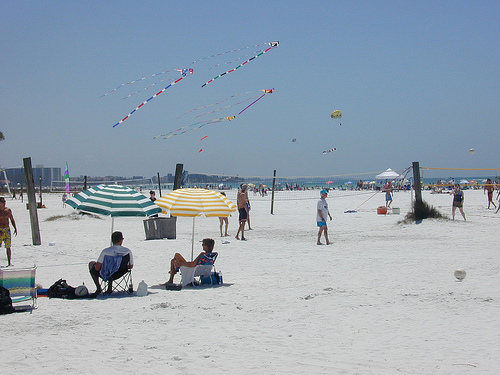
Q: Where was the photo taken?
A: It was taken at the beach.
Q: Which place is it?
A: It is a beach.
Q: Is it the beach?
A: Yes, it is the beach.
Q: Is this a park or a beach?
A: It is a beach.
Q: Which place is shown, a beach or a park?
A: It is a beach.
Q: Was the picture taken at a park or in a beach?
A: It was taken at a beach.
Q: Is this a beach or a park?
A: It is a beach.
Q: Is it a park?
A: No, it is a beach.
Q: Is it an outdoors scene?
A: Yes, it is outdoors.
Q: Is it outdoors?
A: Yes, it is outdoors.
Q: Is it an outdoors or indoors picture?
A: It is outdoors.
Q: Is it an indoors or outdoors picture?
A: It is outdoors.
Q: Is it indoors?
A: No, it is outdoors.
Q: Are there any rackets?
A: No, there are no rackets.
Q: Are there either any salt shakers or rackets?
A: No, there are no rackets or salt shakers.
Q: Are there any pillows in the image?
A: No, there are no pillows.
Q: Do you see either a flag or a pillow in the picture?
A: No, there are no pillows or flags.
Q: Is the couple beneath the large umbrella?
A: Yes, the couple is beneath the umbrella.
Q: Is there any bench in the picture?
A: No, there are no benches.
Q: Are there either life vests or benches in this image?
A: No, there are no benches or life vests.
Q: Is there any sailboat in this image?
A: No, there are no sailboats.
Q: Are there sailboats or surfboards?
A: No, there are no sailboats or surfboards.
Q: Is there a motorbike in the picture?
A: No, there are no motorcycles.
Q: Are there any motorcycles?
A: No, there are no motorcycles.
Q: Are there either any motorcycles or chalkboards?
A: No, there are no motorcycles or chalkboards.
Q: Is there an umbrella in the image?
A: Yes, there is an umbrella.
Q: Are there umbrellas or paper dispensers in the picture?
A: Yes, there is an umbrella.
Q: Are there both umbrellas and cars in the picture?
A: No, there is an umbrella but no cars.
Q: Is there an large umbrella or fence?
A: Yes, there is a large umbrella.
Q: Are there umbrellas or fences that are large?
A: Yes, the umbrella is large.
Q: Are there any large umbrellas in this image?
A: Yes, there is a large umbrella.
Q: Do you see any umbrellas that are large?
A: Yes, there is an umbrella that is large.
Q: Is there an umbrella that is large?
A: Yes, there is an umbrella that is large.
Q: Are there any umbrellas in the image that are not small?
A: Yes, there is a large umbrella.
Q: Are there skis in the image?
A: No, there are no skis.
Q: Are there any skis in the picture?
A: No, there are no skis.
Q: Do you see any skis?
A: No, there are no skis.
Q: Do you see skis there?
A: No, there are no skis.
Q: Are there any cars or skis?
A: No, there are no skis or cars.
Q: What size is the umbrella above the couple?
A: The umbrella is large.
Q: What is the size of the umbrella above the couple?
A: The umbrella is large.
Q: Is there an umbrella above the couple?
A: Yes, there is an umbrella above the couple.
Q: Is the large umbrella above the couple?
A: Yes, the umbrella is above the couple.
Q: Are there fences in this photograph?
A: No, there are no fences.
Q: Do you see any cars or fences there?
A: No, there are no fences or cars.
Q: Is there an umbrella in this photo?
A: Yes, there is an umbrella.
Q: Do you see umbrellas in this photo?
A: Yes, there is an umbrella.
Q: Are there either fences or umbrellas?
A: Yes, there is an umbrella.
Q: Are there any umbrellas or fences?
A: Yes, there is an umbrella.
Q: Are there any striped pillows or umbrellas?
A: Yes, there is a striped umbrella.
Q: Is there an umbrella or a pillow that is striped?
A: Yes, the umbrella is striped.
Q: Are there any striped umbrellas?
A: Yes, there is a striped umbrella.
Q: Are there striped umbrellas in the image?
A: Yes, there is a striped umbrella.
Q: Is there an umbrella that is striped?
A: Yes, there is an umbrella that is striped.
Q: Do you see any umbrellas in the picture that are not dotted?
A: Yes, there is a striped umbrella.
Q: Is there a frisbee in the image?
A: No, there are no frisbees.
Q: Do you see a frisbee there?
A: No, there are no frisbees.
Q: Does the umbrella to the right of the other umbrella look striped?
A: Yes, the umbrella is striped.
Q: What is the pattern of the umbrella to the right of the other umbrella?
A: The umbrella is striped.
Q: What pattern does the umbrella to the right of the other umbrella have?
A: The umbrella has striped pattern.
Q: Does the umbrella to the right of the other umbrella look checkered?
A: No, the umbrella is striped.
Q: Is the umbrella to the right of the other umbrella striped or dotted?
A: The umbrella is striped.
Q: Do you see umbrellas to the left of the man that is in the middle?
A: Yes, there is an umbrella to the left of the man.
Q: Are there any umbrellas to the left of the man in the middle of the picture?
A: Yes, there is an umbrella to the left of the man.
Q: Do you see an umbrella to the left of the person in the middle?
A: Yes, there is an umbrella to the left of the man.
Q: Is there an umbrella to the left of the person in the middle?
A: Yes, there is an umbrella to the left of the man.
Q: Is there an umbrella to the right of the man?
A: No, the umbrella is to the left of the man.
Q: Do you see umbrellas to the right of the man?
A: No, the umbrella is to the left of the man.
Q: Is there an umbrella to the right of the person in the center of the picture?
A: No, the umbrella is to the left of the man.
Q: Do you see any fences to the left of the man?
A: No, there is an umbrella to the left of the man.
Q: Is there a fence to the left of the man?
A: No, there is an umbrella to the left of the man.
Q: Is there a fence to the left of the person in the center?
A: No, there is an umbrella to the left of the man.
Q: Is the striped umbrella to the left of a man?
A: Yes, the umbrella is to the left of a man.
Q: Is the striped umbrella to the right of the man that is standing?
A: No, the umbrella is to the left of the man.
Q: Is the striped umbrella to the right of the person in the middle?
A: No, the umbrella is to the left of the man.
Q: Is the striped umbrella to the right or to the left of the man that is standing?
A: The umbrella is to the left of the man.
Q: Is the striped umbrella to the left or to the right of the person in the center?
A: The umbrella is to the left of the man.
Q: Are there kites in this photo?
A: Yes, there is a kite.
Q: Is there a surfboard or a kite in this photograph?
A: Yes, there is a kite.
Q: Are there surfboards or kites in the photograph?
A: Yes, there is a kite.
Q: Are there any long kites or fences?
A: Yes, there is a long kite.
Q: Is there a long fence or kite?
A: Yes, there is a long kite.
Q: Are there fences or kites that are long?
A: Yes, the kite is long.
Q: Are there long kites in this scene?
A: Yes, there is a long kite.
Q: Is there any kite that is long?
A: Yes, there is a kite that is long.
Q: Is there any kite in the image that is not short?
A: Yes, there is a long kite.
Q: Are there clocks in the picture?
A: No, there are no clocks.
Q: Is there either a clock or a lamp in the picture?
A: No, there are no clocks or lamps.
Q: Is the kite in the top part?
A: Yes, the kite is in the top of the image.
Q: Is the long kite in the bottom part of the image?
A: No, the kite is in the top of the image.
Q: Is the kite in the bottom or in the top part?
A: The kite is in the top of the image.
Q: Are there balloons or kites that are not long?
A: No, there is a kite but it is long.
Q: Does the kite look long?
A: Yes, the kite is long.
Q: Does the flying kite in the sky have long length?
A: Yes, the kite is long.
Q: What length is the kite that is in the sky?
A: The kite is long.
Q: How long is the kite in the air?
A: The kite is long.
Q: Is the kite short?
A: No, the kite is long.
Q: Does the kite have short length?
A: No, the kite is long.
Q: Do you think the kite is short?
A: No, the kite is long.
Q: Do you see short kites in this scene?
A: No, there is a kite but it is long.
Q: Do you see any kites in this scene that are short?
A: No, there is a kite but it is long.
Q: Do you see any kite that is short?
A: No, there is a kite but it is long.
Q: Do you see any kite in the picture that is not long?
A: No, there is a kite but it is long.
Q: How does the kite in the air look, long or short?
A: The kite is long.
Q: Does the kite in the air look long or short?
A: The kite is long.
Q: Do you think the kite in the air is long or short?
A: The kite is long.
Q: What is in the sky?
A: The kite is in the sky.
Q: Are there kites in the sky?
A: Yes, there is a kite in the sky.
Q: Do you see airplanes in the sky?
A: No, there is a kite in the sky.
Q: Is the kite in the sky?
A: Yes, the kite is in the sky.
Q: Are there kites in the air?
A: Yes, there is a kite in the air.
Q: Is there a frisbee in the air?
A: No, there is a kite in the air.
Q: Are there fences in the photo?
A: No, there are no fences.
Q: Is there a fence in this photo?
A: No, there are no fences.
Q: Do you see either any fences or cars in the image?
A: No, there are no fences or cars.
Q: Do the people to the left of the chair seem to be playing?
A: Yes, the people are playing.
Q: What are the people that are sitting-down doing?
A: The people are playing.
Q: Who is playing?
A: The people are playing.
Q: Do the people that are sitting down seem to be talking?
A: No, the people are playing.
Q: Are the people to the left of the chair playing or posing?
A: The people are playing.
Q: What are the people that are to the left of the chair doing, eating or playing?
A: The people are playing.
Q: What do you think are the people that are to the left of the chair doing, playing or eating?
A: The people are playing.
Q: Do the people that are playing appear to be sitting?
A: Yes, the people are sitting.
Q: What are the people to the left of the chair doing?
A: The people are sitting.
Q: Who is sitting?
A: The people are sitting.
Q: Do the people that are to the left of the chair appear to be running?
A: No, the people are sitting.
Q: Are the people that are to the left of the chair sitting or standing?
A: The people are sitting.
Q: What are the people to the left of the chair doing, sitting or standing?
A: The people are sitting.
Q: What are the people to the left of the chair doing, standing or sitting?
A: The people are sitting.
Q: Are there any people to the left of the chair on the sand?
A: Yes, there are people to the left of the chair.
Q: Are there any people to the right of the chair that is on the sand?
A: No, the people are to the left of the chair.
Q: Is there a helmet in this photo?
A: No, there are no helmets.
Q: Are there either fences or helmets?
A: No, there are no helmets or fences.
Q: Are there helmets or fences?
A: No, there are no helmets or fences.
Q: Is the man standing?
A: Yes, the man is standing.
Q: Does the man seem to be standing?
A: Yes, the man is standing.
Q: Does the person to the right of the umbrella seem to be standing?
A: Yes, the man is standing.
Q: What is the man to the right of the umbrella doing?
A: The man is standing.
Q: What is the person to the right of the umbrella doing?
A: The man is standing.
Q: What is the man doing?
A: The man is standing.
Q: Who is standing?
A: The man is standing.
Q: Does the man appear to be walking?
A: No, the man is standing.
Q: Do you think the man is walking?
A: No, the man is standing.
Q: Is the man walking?
A: No, the man is standing.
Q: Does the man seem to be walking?
A: No, the man is standing.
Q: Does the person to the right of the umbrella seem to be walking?
A: No, the man is standing.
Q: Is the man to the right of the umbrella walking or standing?
A: The man is standing.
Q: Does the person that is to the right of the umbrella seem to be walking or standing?
A: The man is standing.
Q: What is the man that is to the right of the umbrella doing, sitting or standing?
A: The man is standing.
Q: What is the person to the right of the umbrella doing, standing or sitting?
A: The man is standing.